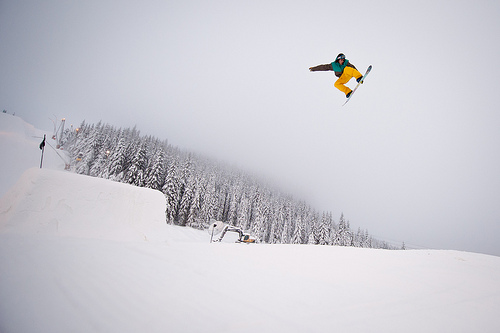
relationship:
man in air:
[307, 52, 363, 97] [2, 0, 499, 255]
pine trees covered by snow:
[55, 116, 404, 261] [47, 254, 468, 326]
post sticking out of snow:
[40, 134, 45, 169] [20, 174, 204, 325]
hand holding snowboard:
[357, 75, 368, 85] [337, 66, 376, 103]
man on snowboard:
[307, 52, 363, 97] [340, 64, 372, 106]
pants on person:
[333, 65, 363, 95] [278, 33, 388, 120]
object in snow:
[206, 221, 258, 245] [19, 257, 494, 325]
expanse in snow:
[0, 104, 498, 330] [1, 112, 495, 329]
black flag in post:
[39, 133, 48, 149] [40, 134, 47, 169]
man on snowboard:
[308, 52, 365, 99] [335, 62, 374, 104]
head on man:
[335, 52, 346, 64] [308, 52, 365, 99]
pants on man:
[337, 67, 367, 96] [322, 49, 367, 89]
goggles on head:
[336, 53, 344, 59] [336, 52, 346, 65]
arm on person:
[310, 62, 332, 72] [308, 52, 363, 95]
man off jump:
[308, 52, 365, 99] [38, 151, 227, 279]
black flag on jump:
[39, 133, 48, 149] [2, 167, 166, 234]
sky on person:
[0, 0, 499, 258] [323, 47, 355, 93]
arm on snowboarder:
[310, 62, 332, 72] [301, 41, 363, 92]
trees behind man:
[91, 125, 399, 248] [308, 52, 365, 99]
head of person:
[335, 52, 346, 64] [304, 57, 377, 95]